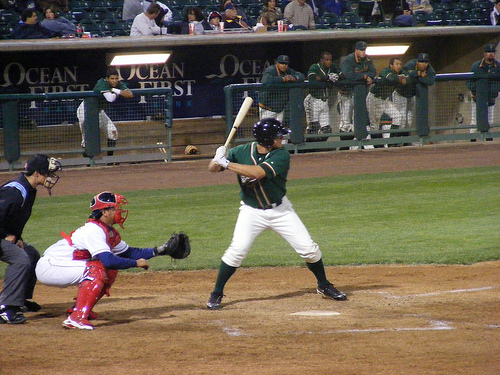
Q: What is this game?
A: Baseball.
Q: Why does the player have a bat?
A: He is a batter.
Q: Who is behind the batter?
A: The catcher.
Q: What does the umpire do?
A: Calls ball and strikes.